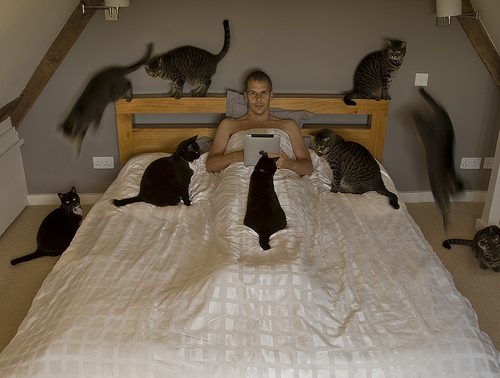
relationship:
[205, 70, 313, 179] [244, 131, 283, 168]
man holding ipad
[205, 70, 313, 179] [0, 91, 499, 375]
man on bed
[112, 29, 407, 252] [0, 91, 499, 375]
cats on bed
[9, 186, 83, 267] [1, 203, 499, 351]
cat on floor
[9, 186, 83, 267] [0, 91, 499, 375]
cat beside bed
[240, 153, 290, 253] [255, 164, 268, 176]
cat has collar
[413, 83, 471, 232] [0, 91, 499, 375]
cat jumping off bed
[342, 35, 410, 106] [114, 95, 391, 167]
cat on headboard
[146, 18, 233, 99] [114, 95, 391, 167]
cat on headboard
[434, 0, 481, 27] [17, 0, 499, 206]
lamp on wall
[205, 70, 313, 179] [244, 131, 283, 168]
man using ipad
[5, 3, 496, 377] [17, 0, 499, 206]
bedroom has wall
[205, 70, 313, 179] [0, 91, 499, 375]
man in bed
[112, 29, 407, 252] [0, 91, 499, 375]
cats in bed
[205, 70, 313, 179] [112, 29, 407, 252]
man with cats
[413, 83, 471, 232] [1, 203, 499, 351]
cat jumping to floor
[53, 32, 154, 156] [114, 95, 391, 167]
cat jumping off headboard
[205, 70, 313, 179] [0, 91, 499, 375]
man laying in bed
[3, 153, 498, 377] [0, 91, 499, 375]
bedspread on bed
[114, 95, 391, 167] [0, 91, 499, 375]
headboard on bed